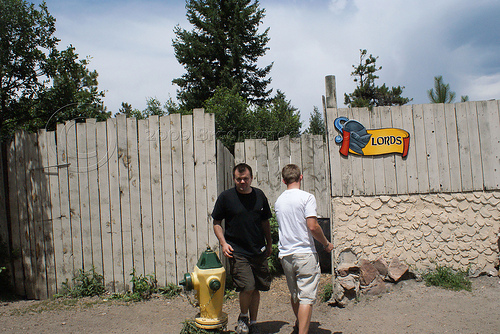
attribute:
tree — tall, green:
[169, 0, 279, 113]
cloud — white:
[18, 0, 485, 126]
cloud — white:
[259, 0, 359, 23]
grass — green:
[417, 260, 474, 294]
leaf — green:
[238, 95, 242, 101]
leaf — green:
[224, 110, 230, 115]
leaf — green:
[227, 104, 231, 110]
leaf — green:
[211, 101, 216, 105]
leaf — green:
[251, 122, 254, 124]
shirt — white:
[273, 186, 322, 260]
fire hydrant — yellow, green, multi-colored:
[178, 243, 234, 332]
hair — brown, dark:
[230, 160, 254, 180]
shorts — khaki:
[279, 250, 322, 306]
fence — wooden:
[0, 71, 481, 299]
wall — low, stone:
[329, 190, 484, 288]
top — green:
[194, 245, 223, 269]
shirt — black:
[208, 185, 273, 255]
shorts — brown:
[225, 240, 274, 291]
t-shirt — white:
[271, 187, 321, 260]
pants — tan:
[280, 251, 321, 303]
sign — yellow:
[329, 113, 411, 161]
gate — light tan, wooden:
[1, 72, 484, 296]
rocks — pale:
[348, 222, 418, 286]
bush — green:
[72, 236, 157, 328]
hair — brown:
[232, 162, 260, 181]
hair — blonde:
[285, 158, 297, 180]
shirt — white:
[271, 187, 326, 260]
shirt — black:
[174, 180, 288, 257]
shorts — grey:
[275, 249, 323, 289]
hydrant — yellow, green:
[154, 220, 246, 325]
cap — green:
[195, 235, 209, 257]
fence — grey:
[45, 83, 208, 246]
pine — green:
[184, 33, 310, 104]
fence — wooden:
[61, 107, 171, 241]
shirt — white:
[269, 199, 354, 278]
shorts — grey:
[287, 251, 368, 322]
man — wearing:
[205, 159, 278, 330]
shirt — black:
[197, 185, 270, 264]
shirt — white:
[277, 188, 318, 262]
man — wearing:
[272, 160, 354, 334]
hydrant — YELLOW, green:
[182, 240, 239, 329]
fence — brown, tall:
[4, 70, 499, 320]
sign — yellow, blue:
[325, 110, 418, 188]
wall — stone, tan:
[334, 190, 499, 280]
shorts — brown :
[216, 235, 281, 296]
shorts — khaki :
[280, 238, 321, 308]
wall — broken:
[327, 237, 420, 316]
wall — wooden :
[321, 101, 496, 201]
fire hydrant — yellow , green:
[175, 242, 231, 330]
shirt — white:
[269, 180, 319, 253]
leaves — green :
[179, 2, 291, 133]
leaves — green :
[196, 17, 278, 133]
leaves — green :
[262, 93, 288, 124]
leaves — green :
[237, 84, 310, 133]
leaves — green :
[175, 8, 270, 128]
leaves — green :
[14, 49, 113, 137]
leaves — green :
[18, 60, 91, 114]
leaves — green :
[9, 5, 82, 109]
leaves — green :
[1, 5, 98, 123]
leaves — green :
[9, 44, 29, 87]